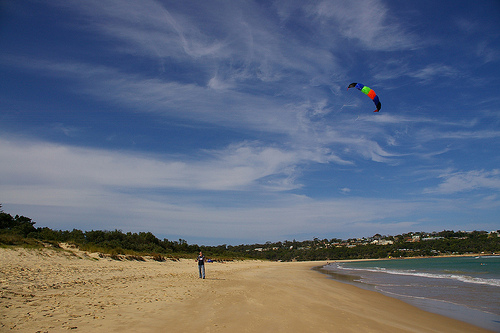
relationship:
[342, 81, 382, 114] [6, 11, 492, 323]
kite in air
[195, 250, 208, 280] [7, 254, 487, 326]
man on beach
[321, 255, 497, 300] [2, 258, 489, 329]
wave approaching shore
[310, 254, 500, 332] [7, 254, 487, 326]
water next to beach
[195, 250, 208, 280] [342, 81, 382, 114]
man flying kite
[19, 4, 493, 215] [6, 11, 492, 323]
clouds in sky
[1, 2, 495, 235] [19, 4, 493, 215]
sky behind clouds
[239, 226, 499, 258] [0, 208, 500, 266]
houses amongst trees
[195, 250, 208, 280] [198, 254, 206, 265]
man wearing shirt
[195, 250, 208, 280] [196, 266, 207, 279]
man wearing jeans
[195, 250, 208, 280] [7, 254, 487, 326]
man walking on beach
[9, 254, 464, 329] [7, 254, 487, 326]
sand on beach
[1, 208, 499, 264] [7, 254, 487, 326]
greenery near beach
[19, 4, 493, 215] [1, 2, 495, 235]
clouds in sky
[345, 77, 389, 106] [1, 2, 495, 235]
kite in sky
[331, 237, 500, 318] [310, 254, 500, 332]
water in water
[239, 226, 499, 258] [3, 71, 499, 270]
houses in distance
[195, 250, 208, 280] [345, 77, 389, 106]
man flying kite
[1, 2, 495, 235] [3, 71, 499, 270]
sky in distance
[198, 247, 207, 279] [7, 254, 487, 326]
man on beach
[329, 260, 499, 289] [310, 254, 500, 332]
wave rolling from water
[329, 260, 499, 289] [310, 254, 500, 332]
wave from water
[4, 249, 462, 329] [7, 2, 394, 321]
land on side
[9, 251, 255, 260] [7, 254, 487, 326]
area by beach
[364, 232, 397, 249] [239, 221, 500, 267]
building in hills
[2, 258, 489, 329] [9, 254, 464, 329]
shore has sand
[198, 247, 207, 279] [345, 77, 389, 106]
man flying kite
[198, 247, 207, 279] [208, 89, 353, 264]
man using string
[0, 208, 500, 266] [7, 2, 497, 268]
trees in back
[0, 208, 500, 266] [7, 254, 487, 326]
trees on beach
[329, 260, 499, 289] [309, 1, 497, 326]
wave on right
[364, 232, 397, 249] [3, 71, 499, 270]
building in distance